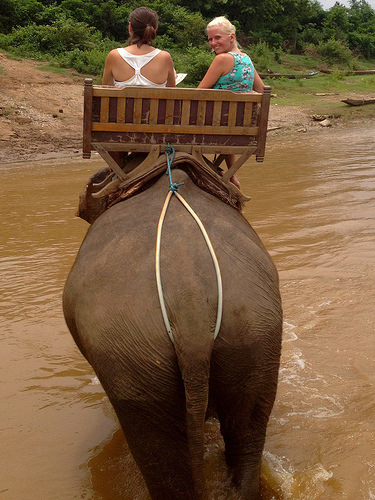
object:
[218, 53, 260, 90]
back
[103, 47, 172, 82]
back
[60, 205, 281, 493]
back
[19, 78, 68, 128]
dirt road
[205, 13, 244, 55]
hair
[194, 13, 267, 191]
woman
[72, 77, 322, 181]
bench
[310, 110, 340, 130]
rocks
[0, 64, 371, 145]
ground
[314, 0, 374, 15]
sky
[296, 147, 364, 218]
water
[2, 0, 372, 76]
trees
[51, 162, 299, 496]
elephant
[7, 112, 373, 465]
water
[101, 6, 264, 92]
people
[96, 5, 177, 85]
woman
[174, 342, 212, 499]
tail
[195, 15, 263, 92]
person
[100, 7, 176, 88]
person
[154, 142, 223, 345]
cord